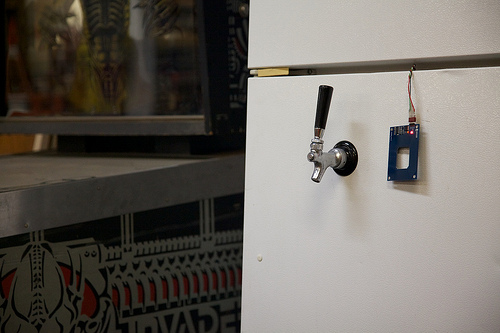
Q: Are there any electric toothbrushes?
A: No, there are no electric toothbrushes.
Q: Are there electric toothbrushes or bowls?
A: No, there are no electric toothbrushes or bowls.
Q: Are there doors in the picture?
A: Yes, there is a door.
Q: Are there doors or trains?
A: Yes, there is a door.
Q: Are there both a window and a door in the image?
A: No, there is a door but no windows.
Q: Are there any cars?
A: No, there are no cars.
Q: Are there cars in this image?
A: No, there are no cars.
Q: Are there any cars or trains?
A: No, there are no cars or trains.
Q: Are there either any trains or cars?
A: No, there are no cars or trains.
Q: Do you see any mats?
A: No, there are no mats.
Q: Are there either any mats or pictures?
A: No, there are no mats or pictures.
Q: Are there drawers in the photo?
A: No, there are no drawers.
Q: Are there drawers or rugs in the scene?
A: No, there are no drawers or rugs.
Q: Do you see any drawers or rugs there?
A: No, there are no drawers or rugs.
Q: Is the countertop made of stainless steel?
A: Yes, the countertop is made of stainless steel.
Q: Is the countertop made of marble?
A: No, the countertop is made of stainless steel.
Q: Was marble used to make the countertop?
A: No, the countertop is made of stainless steel.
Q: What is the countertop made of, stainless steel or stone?
A: The countertop is made of stainless steel.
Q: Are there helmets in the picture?
A: No, there are no helmets.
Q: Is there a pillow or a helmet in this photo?
A: No, there are no helmets or pillows.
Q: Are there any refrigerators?
A: Yes, there is a refrigerator.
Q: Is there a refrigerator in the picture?
A: Yes, there is a refrigerator.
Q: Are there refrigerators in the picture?
A: Yes, there is a refrigerator.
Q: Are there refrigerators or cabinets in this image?
A: Yes, there is a refrigerator.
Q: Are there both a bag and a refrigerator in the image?
A: No, there is a refrigerator but no bags.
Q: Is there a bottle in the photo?
A: No, there are no bottles.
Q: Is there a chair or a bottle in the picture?
A: No, there are no bottles or chairs.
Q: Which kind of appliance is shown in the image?
A: The appliance is a refrigerator.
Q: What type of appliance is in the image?
A: The appliance is a refrigerator.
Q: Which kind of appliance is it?
A: The appliance is a refrigerator.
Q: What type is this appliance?
A: That is a refrigerator.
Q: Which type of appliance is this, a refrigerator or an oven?
A: That is a refrigerator.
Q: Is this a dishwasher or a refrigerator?
A: This is a refrigerator.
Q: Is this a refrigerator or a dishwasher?
A: This is a refrigerator.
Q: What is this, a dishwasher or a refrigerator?
A: This is a refrigerator.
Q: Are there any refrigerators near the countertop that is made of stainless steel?
A: Yes, there is a refrigerator near the counter top.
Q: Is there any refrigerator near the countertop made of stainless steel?
A: Yes, there is a refrigerator near the counter top.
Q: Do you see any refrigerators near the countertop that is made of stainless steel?
A: Yes, there is a refrigerator near the counter top.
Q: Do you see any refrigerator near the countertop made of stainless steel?
A: Yes, there is a refrigerator near the counter top.